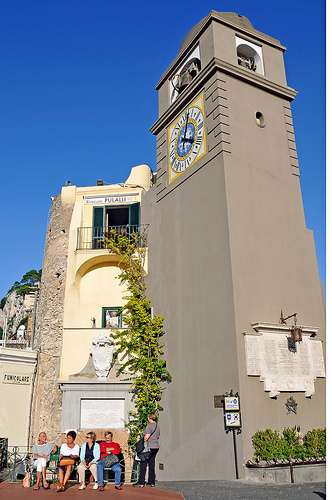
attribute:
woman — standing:
[136, 409, 166, 489]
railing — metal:
[76, 224, 146, 248]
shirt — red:
[100, 441, 119, 459]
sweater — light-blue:
[83, 443, 101, 464]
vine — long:
[110, 226, 165, 409]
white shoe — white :
[76, 481, 89, 488]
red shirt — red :
[101, 443, 122, 453]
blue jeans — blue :
[98, 460, 126, 486]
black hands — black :
[177, 111, 194, 143]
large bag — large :
[134, 434, 153, 461]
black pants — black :
[137, 443, 160, 479]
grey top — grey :
[140, 417, 159, 453]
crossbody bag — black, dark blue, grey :
[132, 434, 149, 455]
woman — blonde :
[135, 400, 163, 486]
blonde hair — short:
[144, 409, 154, 421]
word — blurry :
[85, 197, 104, 206]